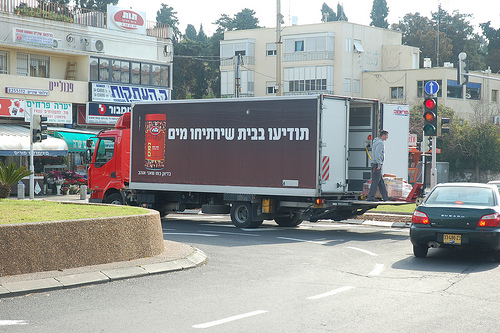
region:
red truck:
[89, 104, 136, 209]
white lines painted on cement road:
[275, 232, 398, 306]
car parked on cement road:
[407, 167, 498, 259]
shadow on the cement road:
[152, 205, 414, 255]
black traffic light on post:
[415, 96, 446, 143]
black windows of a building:
[82, 46, 173, 90]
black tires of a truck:
[224, 202, 264, 229]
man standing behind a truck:
[356, 122, 403, 204]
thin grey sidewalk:
[2, 205, 204, 300]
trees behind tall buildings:
[397, 4, 498, 72]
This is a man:
[366, 122, 396, 208]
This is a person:
[361, 122, 401, 212]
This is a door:
[316, 96, 386, 195]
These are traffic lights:
[416, 77, 445, 209]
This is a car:
[402, 174, 499, 253]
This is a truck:
[91, 84, 392, 233]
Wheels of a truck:
[226, 193, 266, 233]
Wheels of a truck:
[267, 193, 314, 238]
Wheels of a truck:
[98, 183, 140, 218]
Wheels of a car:
[406, 225, 431, 263]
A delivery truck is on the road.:
[70, 80, 420, 253]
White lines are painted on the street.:
[156, 265, 366, 325]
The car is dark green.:
[400, 180, 496, 261]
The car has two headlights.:
[410, 205, 495, 225]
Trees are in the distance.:
[150, 1, 265, 21]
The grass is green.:
[3, 201, 83, 216]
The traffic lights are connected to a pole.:
[20, 100, 48, 200]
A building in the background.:
[0, 5, 178, 195]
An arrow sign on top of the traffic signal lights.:
[410, 72, 450, 137]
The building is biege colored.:
[206, 12, 496, 94]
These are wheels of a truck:
[224, 197, 269, 232]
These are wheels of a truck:
[275, 197, 314, 229]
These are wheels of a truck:
[103, 182, 125, 207]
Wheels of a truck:
[149, 193, 181, 222]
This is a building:
[219, 18, 431, 99]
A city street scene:
[3, 2, 498, 329]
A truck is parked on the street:
[85, 91, 412, 228]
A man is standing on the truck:
[364, 126, 397, 202]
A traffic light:
[418, 93, 445, 138]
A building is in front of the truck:
[1, 0, 174, 197]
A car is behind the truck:
[405, 175, 498, 263]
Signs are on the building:
[0, 78, 171, 125]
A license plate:
[440, 231, 464, 246]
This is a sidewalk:
[2, 240, 205, 301]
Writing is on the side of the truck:
[166, 122, 312, 146]